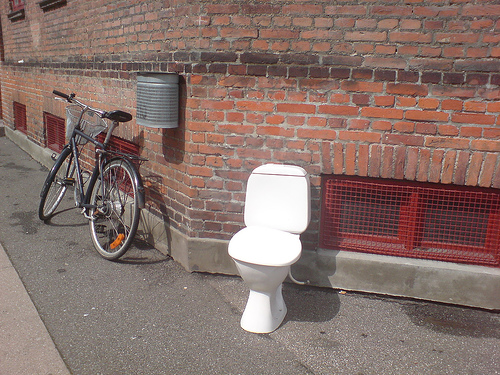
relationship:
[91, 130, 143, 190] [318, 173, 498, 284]
panes on window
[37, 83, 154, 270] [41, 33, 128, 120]
bicycle on wall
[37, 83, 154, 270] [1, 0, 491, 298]
bicycle against building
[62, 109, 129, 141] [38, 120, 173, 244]
basket is on bicycle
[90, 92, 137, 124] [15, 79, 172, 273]
seat is on bicycle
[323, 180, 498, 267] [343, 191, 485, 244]
red cover is on window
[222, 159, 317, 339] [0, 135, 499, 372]
toilet is on street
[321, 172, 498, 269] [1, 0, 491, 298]
grates is on building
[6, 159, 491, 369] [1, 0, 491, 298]
sidewalk next to building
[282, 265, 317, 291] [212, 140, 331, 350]
tube is on toilet